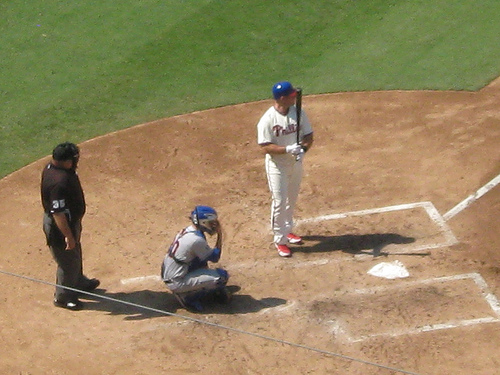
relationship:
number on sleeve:
[51, 199, 66, 211] [46, 184, 68, 211]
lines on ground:
[270, 198, 498, 344] [1, 89, 498, 374]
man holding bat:
[258, 53, 332, 293] [293, 90, 303, 160]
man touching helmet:
[155, 209, 231, 303] [187, 204, 222, 239]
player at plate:
[252, 82, 314, 258] [368, 264, 414, 289]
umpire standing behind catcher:
[38, 141, 97, 311] [159, 205, 229, 312]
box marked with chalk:
[315, 269, 497, 348] [270, 202, 497, 348]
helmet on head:
[272, 80, 297, 100] [274, 78, 299, 107]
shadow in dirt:
[296, 227, 416, 266] [239, 143, 411, 325]